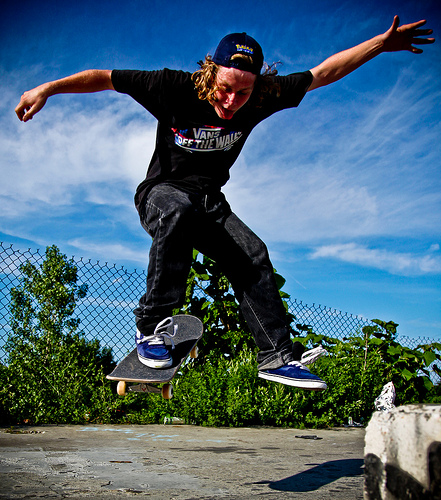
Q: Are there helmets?
A: No, there are no helmets.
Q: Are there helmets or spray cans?
A: No, there are no helmets or spray cans.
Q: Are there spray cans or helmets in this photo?
A: No, there are no helmets or spray cans.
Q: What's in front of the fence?
A: The shrubs are in front of the fence.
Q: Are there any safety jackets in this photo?
A: No, there are no safety jackets.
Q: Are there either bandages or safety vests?
A: No, there are no safety vests or bandages.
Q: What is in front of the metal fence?
A: The shrubs are in front of the fence.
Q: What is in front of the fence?
A: The shrubs are in front of the fence.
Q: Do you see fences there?
A: Yes, there is a fence.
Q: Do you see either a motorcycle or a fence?
A: Yes, there is a fence.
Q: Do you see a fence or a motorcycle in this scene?
A: Yes, there is a fence.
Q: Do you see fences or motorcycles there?
A: Yes, there is a fence.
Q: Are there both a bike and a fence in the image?
A: No, there is a fence but no bikes.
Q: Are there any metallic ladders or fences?
A: Yes, there is a metal fence.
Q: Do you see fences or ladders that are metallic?
A: Yes, the fence is metallic.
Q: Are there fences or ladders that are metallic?
A: Yes, the fence is metallic.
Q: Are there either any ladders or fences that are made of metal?
A: Yes, the fence is made of metal.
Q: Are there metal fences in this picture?
A: Yes, there is a metal fence.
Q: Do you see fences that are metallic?
A: Yes, there is a fence that is metallic.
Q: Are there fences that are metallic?
A: Yes, there is a fence that is metallic.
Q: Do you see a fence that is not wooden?
A: Yes, there is a metallic fence.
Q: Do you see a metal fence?
A: Yes, there is a fence that is made of metal.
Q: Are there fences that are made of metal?
A: Yes, there is a fence that is made of metal.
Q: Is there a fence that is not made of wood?
A: Yes, there is a fence that is made of metal.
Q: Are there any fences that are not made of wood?
A: Yes, there is a fence that is made of metal.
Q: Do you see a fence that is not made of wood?
A: Yes, there is a fence that is made of metal.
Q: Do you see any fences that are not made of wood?
A: Yes, there is a fence that is made of metal.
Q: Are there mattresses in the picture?
A: No, there are no mattresses.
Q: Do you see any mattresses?
A: No, there are no mattresses.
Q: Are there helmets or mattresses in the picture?
A: No, there are no mattresses or helmets.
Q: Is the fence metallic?
A: Yes, the fence is metallic.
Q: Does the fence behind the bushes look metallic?
A: Yes, the fence is metallic.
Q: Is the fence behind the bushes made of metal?
A: Yes, the fence is made of metal.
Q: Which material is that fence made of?
A: The fence is made of metal.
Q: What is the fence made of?
A: The fence is made of metal.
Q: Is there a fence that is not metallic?
A: No, there is a fence but it is metallic.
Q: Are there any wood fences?
A: No, there is a fence but it is made of metal.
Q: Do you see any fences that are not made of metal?
A: No, there is a fence but it is made of metal.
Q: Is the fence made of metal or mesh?
A: The fence is made of metal.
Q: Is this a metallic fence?
A: Yes, this is a metallic fence.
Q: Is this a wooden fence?
A: No, this is a metallic fence.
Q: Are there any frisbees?
A: No, there are no frisbees.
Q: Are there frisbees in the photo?
A: No, there are no frisbees.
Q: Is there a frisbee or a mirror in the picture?
A: No, there are no frisbees or mirrors.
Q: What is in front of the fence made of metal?
A: The bushes are in front of the fence.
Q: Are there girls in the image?
A: No, there are no girls.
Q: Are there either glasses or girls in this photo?
A: No, there are no girls or glasses.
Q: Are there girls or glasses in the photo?
A: No, there are no girls or glasses.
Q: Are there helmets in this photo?
A: No, there are no helmets.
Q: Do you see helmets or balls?
A: No, there are no helmets or balls.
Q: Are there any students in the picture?
A: No, there are no students.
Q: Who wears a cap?
A: The man wears a cap.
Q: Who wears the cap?
A: The man wears a cap.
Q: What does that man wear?
A: The man wears a cap.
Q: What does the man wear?
A: The man wears a cap.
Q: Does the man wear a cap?
A: Yes, the man wears a cap.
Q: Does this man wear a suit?
A: No, the man wears a cap.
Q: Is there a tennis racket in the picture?
A: No, there are no rackets.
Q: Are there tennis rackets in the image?
A: No, there are no tennis rackets.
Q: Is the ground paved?
A: Yes, the ground is paved.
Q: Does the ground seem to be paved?
A: Yes, the ground is paved.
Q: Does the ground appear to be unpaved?
A: No, the ground is paved.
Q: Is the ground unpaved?
A: No, the ground is paved.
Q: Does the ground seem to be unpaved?
A: No, the ground is paved.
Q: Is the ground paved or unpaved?
A: The ground is paved.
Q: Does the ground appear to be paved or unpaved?
A: The ground is paved.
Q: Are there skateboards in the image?
A: Yes, there is a skateboard.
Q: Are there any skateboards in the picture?
A: Yes, there is a skateboard.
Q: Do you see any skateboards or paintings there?
A: Yes, there is a skateboard.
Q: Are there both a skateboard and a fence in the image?
A: Yes, there are both a skateboard and a fence.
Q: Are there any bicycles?
A: No, there are no bicycles.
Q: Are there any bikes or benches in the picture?
A: No, there are no bikes or benches.